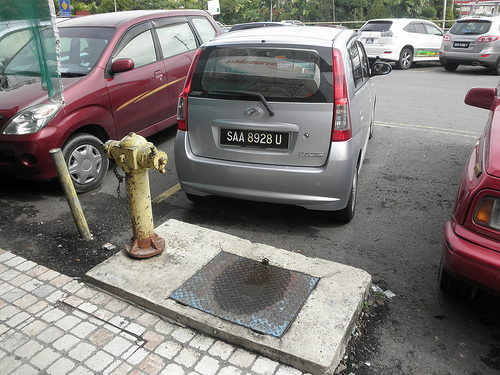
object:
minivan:
[170, 23, 378, 223]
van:
[0, 10, 219, 191]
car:
[356, 18, 445, 72]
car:
[441, 17, 499, 69]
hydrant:
[99, 131, 170, 259]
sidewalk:
[2, 247, 314, 375]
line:
[152, 183, 181, 203]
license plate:
[219, 126, 289, 148]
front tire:
[64, 137, 110, 193]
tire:
[396, 48, 414, 69]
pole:
[47, 146, 95, 240]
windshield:
[193, 46, 333, 105]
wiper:
[210, 89, 272, 118]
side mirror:
[369, 61, 391, 77]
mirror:
[113, 59, 135, 74]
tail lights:
[331, 47, 353, 141]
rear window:
[452, 21, 490, 35]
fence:
[105, 0, 499, 24]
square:
[82, 217, 376, 375]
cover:
[168, 254, 321, 337]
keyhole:
[303, 131, 309, 139]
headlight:
[3, 100, 67, 137]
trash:
[371, 281, 399, 311]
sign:
[58, 2, 71, 16]